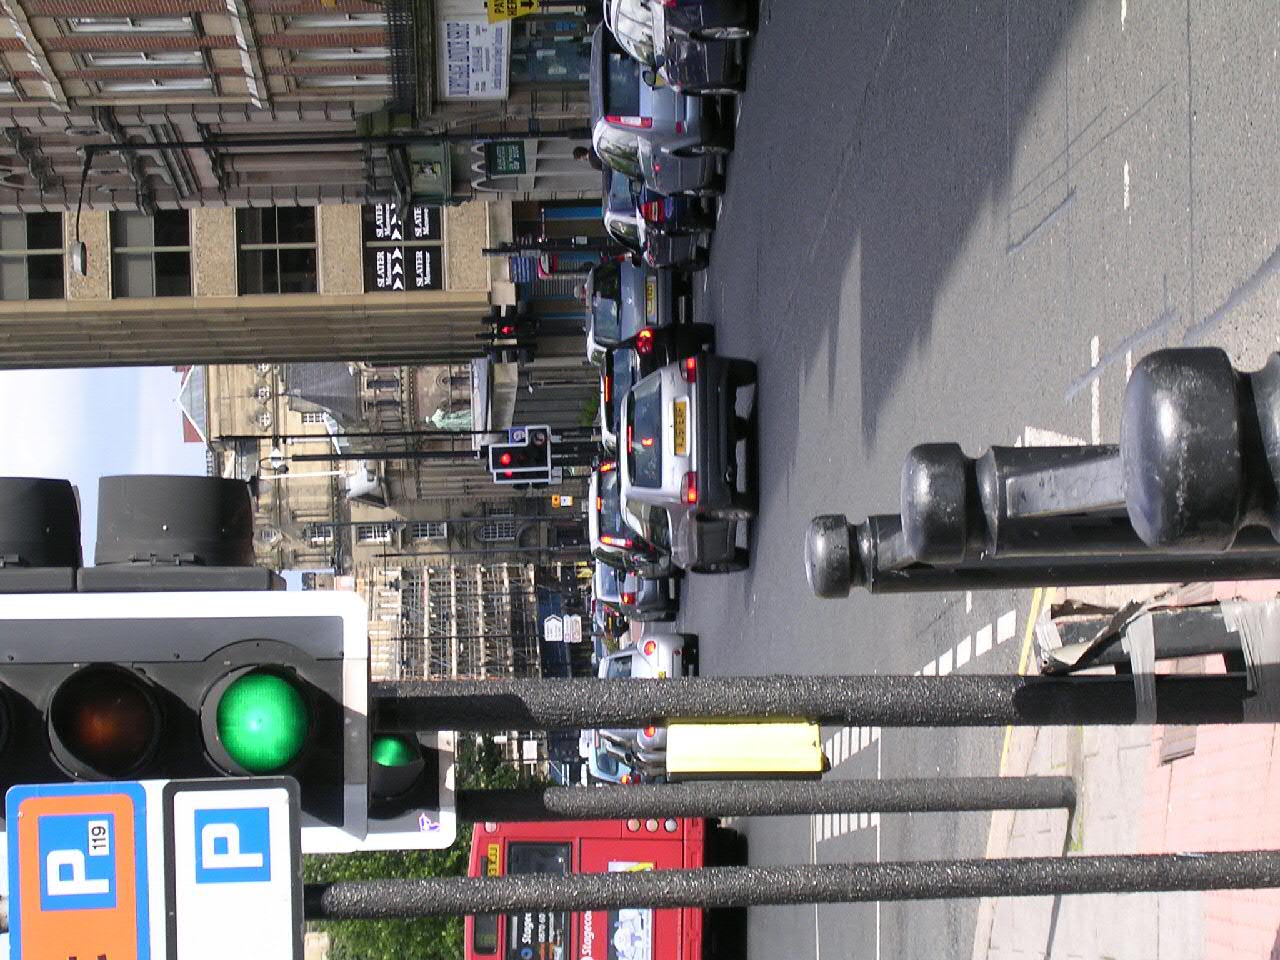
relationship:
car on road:
[527, 120, 706, 319] [722, 297, 1017, 373]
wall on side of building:
[0, 921, 563, 957] [6, 214, 522, 360]